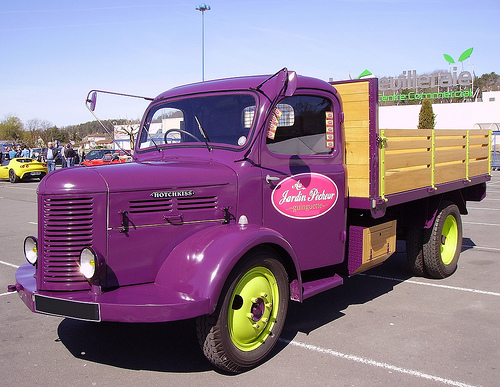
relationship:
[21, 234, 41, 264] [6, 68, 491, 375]
headlight on truck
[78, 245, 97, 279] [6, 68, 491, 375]
headlight on truck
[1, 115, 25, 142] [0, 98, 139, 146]
tree in distance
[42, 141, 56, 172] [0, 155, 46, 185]
man near car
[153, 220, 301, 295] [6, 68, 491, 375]
fender of truck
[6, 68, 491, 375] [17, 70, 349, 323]
truck has paint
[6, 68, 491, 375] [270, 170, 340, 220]
truck has logo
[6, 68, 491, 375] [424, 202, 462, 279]
truck has wheel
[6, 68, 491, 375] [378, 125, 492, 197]
truck has bed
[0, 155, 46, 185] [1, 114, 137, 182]
car in background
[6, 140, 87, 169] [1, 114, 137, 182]
people in background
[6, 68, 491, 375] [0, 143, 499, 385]
truck in lot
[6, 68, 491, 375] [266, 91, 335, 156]
truck has window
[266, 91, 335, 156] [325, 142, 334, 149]
window has sticker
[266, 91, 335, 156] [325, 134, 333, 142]
window has sticker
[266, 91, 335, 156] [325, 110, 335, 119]
window has sticker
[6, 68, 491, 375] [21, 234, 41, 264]
truck has headlight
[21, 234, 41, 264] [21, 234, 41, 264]
headlight has headlight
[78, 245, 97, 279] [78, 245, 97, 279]
headlight has headlight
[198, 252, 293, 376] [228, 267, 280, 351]
tire with rim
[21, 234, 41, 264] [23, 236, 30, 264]
light has rim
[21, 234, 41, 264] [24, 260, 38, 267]
light has rim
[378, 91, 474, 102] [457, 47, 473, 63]
sign has highlight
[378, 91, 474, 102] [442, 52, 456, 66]
sign has highlight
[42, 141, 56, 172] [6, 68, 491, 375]
man staring at truck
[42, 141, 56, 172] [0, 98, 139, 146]
man in distance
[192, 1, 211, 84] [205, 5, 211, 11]
streetlight has lamp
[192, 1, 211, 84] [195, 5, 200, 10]
streetlight has lamp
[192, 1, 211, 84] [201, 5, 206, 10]
streetlight has lamp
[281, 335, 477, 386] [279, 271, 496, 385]
line of space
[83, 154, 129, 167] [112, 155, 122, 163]
car has decor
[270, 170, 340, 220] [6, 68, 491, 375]
sign on truck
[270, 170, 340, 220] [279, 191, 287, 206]
sign has letter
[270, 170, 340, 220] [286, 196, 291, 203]
sign has letter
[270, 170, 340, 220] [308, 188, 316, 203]
sign has letter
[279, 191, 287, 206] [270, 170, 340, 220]
letter on sign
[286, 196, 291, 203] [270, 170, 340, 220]
letter on sign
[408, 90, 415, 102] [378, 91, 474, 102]
letter on sign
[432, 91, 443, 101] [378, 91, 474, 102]
letter on sign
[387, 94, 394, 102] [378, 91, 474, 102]
letter on sign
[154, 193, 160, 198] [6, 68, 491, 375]
letter on truck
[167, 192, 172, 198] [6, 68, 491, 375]
letter on truck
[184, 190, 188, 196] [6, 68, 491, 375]
letter on truck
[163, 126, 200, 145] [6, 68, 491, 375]
wheel in truck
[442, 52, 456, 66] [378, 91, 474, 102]
leaf on sign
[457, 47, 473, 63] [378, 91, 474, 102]
leaf on sign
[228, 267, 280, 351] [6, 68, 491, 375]
hubcap on truck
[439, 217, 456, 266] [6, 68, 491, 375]
hubcap on truck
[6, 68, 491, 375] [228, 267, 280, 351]
truck has hubcap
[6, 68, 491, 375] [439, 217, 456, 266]
truck has hubcap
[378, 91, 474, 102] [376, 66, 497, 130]
sign in background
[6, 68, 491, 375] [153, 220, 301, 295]
truck has fender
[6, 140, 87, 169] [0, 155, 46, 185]
people look at car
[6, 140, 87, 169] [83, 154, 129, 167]
people look at car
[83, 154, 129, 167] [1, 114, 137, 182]
car in background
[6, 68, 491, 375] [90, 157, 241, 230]
truck has door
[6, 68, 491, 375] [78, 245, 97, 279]
truck has headlight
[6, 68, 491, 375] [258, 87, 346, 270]
truck has door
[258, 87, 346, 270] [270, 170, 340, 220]
door has sign